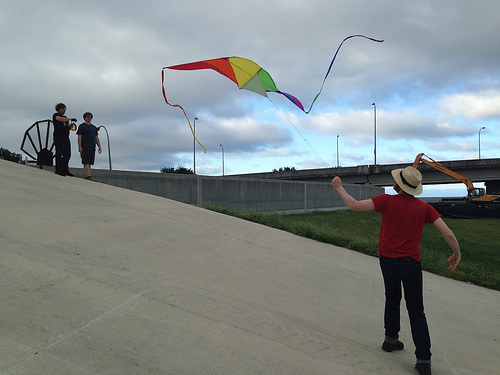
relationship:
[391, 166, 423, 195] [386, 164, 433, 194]
cap wearing by cap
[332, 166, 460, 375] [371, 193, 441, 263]
boy wearing shirt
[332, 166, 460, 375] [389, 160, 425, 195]
boy wearing hat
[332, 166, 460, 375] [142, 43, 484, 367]
boy flying kite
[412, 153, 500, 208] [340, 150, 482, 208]
crane under bridge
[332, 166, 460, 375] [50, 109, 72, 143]
boy wearing shirt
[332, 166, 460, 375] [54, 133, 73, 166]
boy wearing pants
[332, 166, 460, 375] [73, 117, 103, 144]
boy wearing shirt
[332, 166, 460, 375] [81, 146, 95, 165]
boy wearing clothing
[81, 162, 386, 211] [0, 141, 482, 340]
fence in park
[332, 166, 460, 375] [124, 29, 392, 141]
boy flying kite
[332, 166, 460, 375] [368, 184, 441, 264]
boy in shirt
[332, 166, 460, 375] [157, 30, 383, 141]
boy flying kite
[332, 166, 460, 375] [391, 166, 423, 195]
boy wearing cap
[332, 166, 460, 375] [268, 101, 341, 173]
boy holding string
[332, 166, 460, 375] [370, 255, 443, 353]
boy wearing pants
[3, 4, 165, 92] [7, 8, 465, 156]
clouds in sky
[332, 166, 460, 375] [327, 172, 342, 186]
boy has hand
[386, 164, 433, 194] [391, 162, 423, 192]
cap on head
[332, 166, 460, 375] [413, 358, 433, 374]
boy wearing shoe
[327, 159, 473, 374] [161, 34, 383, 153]
boy holding kite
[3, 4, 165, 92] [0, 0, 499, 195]
clouds in sky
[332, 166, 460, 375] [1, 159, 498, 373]
boy on slope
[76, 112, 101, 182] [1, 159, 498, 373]
adult on slope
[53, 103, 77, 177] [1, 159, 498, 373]
adult on slope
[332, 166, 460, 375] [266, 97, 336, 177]
boy holding rope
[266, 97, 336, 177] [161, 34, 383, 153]
rope attached to kite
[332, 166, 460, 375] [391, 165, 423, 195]
boy wearing hat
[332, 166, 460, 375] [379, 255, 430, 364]
boy wearing pants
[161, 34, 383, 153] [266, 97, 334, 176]
kite attached to rope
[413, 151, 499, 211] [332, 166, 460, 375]
crane behind boy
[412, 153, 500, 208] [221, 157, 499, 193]
crane working near bridge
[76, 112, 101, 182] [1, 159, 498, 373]
adult standing on slope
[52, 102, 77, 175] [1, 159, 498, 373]
adult standing on slope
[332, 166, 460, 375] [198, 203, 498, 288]
boy standing in front of yard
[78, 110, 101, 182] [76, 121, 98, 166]
adult wearing clothing